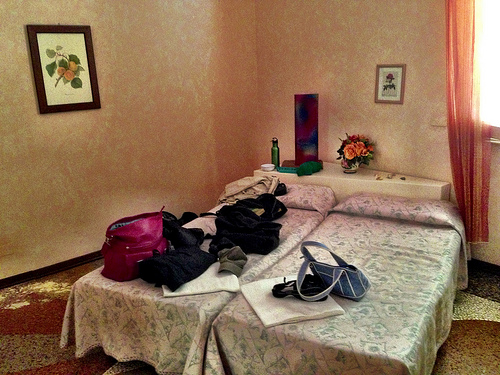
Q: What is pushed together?
A: Two twin beds.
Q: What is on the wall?
A: A picture of flowers.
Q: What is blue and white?
A: A ladies bag.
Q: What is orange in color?
A: The curtain.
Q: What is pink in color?
A: The drapes.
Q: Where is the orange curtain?
A: On the window.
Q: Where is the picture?
A: On the wall.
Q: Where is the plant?
A: In the pitcher.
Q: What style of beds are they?
A: Twin.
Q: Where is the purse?
A: On the bed.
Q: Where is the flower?
A: On the headboard.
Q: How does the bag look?
A: Open.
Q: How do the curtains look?
A: Sheer.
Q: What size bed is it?
A: Twin.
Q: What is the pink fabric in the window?
A: Curtain.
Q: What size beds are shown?
A: Twin.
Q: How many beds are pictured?
A: Two.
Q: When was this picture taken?
A: During the day.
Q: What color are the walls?
A: Pink.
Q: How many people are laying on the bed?
A: Zero.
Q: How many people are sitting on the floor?
A: Zero.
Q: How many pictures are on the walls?
A: Two.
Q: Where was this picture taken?
A: In a bedroom.